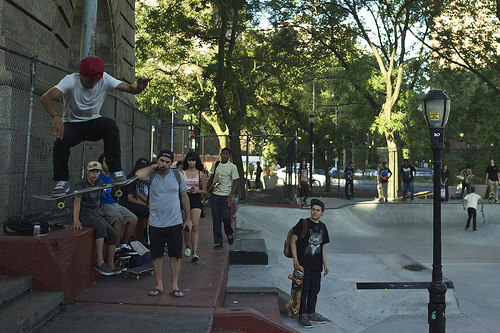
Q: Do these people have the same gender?
A: No, they are both male and female.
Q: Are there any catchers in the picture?
A: No, there are no catchers.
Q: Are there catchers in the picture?
A: No, there are no catchers.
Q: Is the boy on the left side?
A: Yes, the boy is on the left of the image.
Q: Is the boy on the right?
A: No, the boy is on the left of the image.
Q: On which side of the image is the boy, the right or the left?
A: The boy is on the left of the image.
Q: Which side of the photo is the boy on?
A: The boy is on the left of the image.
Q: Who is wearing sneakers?
A: The boy is wearing sneakers.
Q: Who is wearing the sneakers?
A: The boy is wearing sneakers.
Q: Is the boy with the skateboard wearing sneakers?
A: Yes, the boy is wearing sneakers.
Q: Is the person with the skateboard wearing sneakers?
A: Yes, the boy is wearing sneakers.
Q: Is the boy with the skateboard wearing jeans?
A: No, the boy is wearing sneakers.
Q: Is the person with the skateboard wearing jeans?
A: No, the boy is wearing sneakers.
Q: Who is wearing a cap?
A: The boy is wearing a cap.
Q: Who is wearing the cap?
A: The boy is wearing a cap.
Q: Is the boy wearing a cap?
A: Yes, the boy is wearing a cap.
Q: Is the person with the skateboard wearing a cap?
A: Yes, the boy is wearing a cap.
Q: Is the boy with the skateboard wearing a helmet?
A: No, the boy is wearing a cap.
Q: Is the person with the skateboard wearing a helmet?
A: No, the boy is wearing a cap.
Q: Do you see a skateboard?
A: Yes, there is a skateboard.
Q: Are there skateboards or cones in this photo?
A: Yes, there is a skateboard.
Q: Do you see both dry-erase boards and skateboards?
A: No, there is a skateboard but no dry-erase boards.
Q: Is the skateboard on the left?
A: Yes, the skateboard is on the left of the image.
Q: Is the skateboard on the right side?
A: No, the skateboard is on the left of the image.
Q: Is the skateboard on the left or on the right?
A: The skateboard is on the left of the image.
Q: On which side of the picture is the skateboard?
A: The skateboard is on the left of the image.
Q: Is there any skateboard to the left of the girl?
A: Yes, there is a skateboard to the left of the girl.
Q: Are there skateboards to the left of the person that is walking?
A: Yes, there is a skateboard to the left of the girl.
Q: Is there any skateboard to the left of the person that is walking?
A: Yes, there is a skateboard to the left of the girl.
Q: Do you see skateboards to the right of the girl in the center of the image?
A: No, the skateboard is to the left of the girl.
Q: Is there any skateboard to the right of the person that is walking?
A: No, the skateboard is to the left of the girl.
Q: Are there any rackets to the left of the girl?
A: No, there is a skateboard to the left of the girl.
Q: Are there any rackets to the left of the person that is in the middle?
A: No, there is a skateboard to the left of the girl.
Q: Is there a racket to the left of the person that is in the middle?
A: No, there is a skateboard to the left of the girl.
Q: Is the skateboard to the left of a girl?
A: Yes, the skateboard is to the left of a girl.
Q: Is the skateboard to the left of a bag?
A: No, the skateboard is to the left of a girl.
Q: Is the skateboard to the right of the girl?
A: No, the skateboard is to the left of the girl.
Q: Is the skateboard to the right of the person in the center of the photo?
A: No, the skateboard is to the left of the girl.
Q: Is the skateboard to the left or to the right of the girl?
A: The skateboard is to the left of the girl.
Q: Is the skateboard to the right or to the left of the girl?
A: The skateboard is to the left of the girl.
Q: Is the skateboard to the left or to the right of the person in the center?
A: The skateboard is to the left of the girl.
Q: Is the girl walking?
A: Yes, the girl is walking.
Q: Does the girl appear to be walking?
A: Yes, the girl is walking.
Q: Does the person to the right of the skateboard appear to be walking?
A: Yes, the girl is walking.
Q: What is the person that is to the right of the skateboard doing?
A: The girl is walking.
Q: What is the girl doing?
A: The girl is walking.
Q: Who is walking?
A: The girl is walking.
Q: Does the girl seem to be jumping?
A: No, the girl is walking.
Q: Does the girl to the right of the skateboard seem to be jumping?
A: No, the girl is walking.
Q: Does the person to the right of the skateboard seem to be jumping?
A: No, the girl is walking.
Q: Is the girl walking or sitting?
A: The girl is walking.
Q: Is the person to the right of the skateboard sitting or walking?
A: The girl is walking.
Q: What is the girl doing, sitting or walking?
A: The girl is walking.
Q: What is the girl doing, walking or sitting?
A: The girl is walking.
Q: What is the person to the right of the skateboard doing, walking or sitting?
A: The girl is walking.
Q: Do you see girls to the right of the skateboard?
A: Yes, there is a girl to the right of the skateboard.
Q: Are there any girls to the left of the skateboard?
A: No, the girl is to the right of the skateboard.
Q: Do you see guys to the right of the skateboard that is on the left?
A: No, there is a girl to the right of the skateboard.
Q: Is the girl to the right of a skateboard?
A: Yes, the girl is to the right of a skateboard.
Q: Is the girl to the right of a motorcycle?
A: No, the girl is to the right of a skateboard.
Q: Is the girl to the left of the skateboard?
A: No, the girl is to the right of the skateboard.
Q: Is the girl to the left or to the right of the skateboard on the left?
A: The girl is to the right of the skateboard.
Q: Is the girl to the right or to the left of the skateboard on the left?
A: The girl is to the right of the skateboard.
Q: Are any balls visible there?
A: No, there are no balls.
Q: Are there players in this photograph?
A: No, there are no players.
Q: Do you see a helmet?
A: No, there are no helmets.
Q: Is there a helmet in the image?
A: No, there are no helmets.